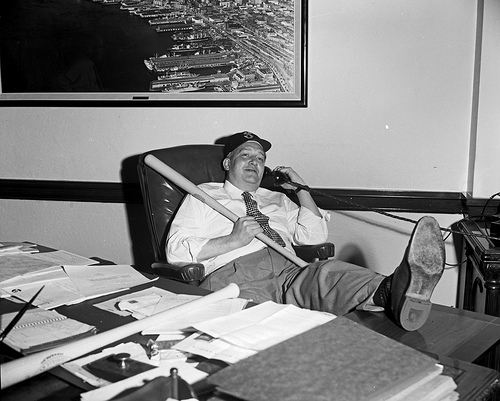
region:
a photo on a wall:
[1, 5, 313, 113]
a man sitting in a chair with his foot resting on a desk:
[144, 134, 444, 329]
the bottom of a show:
[399, 215, 449, 332]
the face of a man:
[237, 137, 265, 182]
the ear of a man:
[217, 153, 237, 174]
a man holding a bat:
[136, 125, 328, 266]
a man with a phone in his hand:
[217, 121, 344, 204]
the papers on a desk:
[1, 244, 136, 323]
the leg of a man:
[281, 255, 388, 313]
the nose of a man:
[245, 150, 263, 169]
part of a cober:
[308, 367, 320, 384]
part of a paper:
[176, 338, 194, 373]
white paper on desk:
[33, 245, 99, 269]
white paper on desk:
[0, 252, 55, 283]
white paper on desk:
[56, 260, 158, 292]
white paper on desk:
[7, 276, 106, 309]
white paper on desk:
[91, 286, 177, 317]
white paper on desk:
[192, 300, 337, 357]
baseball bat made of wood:
[139, 151, 309, 268]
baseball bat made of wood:
[9, 283, 241, 397]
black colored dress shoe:
[386, 213, 448, 332]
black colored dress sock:
[373, 272, 393, 309]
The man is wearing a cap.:
[223, 130, 272, 191]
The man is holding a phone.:
[213, 128, 310, 201]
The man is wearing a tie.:
[216, 132, 293, 254]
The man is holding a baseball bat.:
[143, 130, 318, 277]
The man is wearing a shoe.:
[388, 211, 447, 333]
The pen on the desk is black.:
[1, 278, 49, 345]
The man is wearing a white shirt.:
[163, 130, 332, 278]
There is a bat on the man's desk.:
[1, 278, 240, 395]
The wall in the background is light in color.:
[326, 12, 416, 109]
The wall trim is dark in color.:
[1, 177, 121, 204]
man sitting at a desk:
[161, 128, 453, 331]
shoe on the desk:
[388, 213, 454, 339]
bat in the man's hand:
[140, 148, 314, 278]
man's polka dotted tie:
[241, 190, 290, 252]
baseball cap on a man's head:
[221, 125, 274, 153]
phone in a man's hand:
[268, 163, 286, 193]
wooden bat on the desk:
[1, 280, 249, 391]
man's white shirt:
[163, 173, 333, 275]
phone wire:
[290, 175, 499, 257]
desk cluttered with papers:
[2, 226, 498, 399]